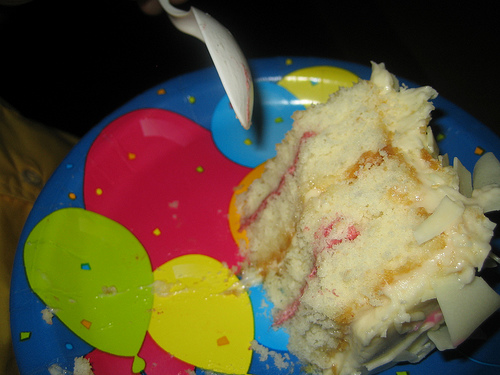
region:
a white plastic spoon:
[153, 0, 257, 134]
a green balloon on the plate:
[20, 204, 160, 374]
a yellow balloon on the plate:
[148, 251, 260, 373]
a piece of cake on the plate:
[220, 55, 499, 373]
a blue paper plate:
[3, 53, 491, 374]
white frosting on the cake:
[318, 58, 499, 374]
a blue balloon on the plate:
[208, 78, 308, 169]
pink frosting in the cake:
[229, 125, 316, 236]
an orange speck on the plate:
[471, 141, 487, 157]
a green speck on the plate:
[191, 158, 208, 177]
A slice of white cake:
[236, 73, 496, 374]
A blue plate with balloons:
[11, 55, 498, 374]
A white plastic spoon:
[155, 0, 258, 132]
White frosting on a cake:
[332, 60, 499, 373]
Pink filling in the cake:
[236, 124, 363, 326]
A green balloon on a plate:
[22, 204, 154, 374]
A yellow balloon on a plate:
[147, 251, 257, 373]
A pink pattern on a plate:
[80, 106, 257, 278]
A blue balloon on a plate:
[211, 78, 308, 168]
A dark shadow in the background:
[0, 0, 498, 143]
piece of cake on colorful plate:
[3, 52, 496, 374]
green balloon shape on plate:
[15, 207, 160, 372]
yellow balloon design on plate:
[137, 249, 254, 374]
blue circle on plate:
[207, 79, 315, 176]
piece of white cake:
[230, 58, 499, 371]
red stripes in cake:
[224, 116, 376, 336]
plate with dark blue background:
[10, 54, 495, 371]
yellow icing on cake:
[343, 38, 498, 373]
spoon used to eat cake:
[151, 1, 297, 144]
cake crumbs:
[235, 332, 300, 374]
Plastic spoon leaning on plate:
[151, 2, 257, 129]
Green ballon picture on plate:
[22, 205, 162, 367]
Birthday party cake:
[243, 77, 494, 362]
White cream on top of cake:
[350, 236, 499, 373]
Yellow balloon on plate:
[141, 253, 261, 370]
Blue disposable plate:
[10, 47, 499, 374]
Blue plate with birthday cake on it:
[11, 48, 499, 373]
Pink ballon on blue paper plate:
[79, 102, 261, 272]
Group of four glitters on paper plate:
[91, 151, 211, 241]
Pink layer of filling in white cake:
[231, 130, 361, 327]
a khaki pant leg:
[0, 103, 82, 373]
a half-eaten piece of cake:
[235, 60, 498, 374]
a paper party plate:
[7, 57, 499, 374]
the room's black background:
[0, 0, 499, 142]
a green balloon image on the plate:
[22, 206, 154, 373]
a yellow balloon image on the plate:
[146, 253, 254, 373]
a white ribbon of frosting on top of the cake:
[426, 274, 498, 351]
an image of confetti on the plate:
[94, 187, 103, 194]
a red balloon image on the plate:
[82, 107, 256, 276]